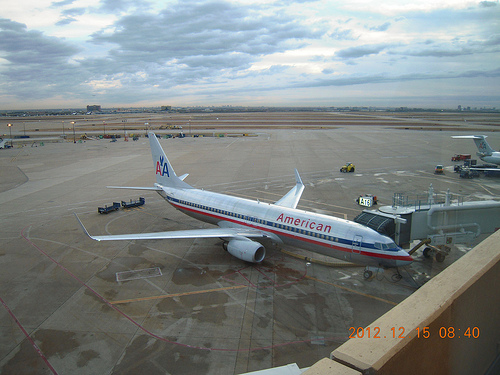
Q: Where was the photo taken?
A: It was taken at the airport.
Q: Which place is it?
A: It is an airport.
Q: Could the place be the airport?
A: Yes, it is the airport.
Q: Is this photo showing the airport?
A: Yes, it is showing the airport.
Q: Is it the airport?
A: Yes, it is the airport.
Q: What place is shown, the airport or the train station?
A: It is the airport.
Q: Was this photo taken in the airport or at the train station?
A: It was taken at the airport.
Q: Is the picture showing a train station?
A: No, the picture is showing an airport.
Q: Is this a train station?
A: No, it is an airport.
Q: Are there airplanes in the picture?
A: Yes, there is an airplane.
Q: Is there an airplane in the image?
A: Yes, there is an airplane.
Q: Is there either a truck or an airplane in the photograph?
A: Yes, there is an airplane.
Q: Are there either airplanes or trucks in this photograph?
A: Yes, there is an airplane.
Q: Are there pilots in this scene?
A: No, there are no pilots.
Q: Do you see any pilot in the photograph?
A: No, there are no pilots.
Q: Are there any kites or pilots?
A: No, there are no pilots or kites.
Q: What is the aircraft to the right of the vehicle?
A: The aircraft is an airplane.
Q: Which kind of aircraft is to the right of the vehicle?
A: The aircraft is an airplane.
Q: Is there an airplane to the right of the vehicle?
A: Yes, there is an airplane to the right of the vehicle.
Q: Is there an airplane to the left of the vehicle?
A: No, the airplane is to the right of the vehicle.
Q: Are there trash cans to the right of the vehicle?
A: No, there is an airplane to the right of the vehicle.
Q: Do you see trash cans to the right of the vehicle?
A: No, there is an airplane to the right of the vehicle.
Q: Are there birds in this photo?
A: No, there are no birds.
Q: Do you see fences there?
A: No, there are no fences.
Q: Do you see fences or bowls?
A: No, there are no fences or bowls.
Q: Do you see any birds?
A: No, there are no birds.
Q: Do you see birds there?
A: No, there are no birds.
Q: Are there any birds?
A: No, there are no birds.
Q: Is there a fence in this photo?
A: No, there are no fences.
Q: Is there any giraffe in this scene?
A: No, there are no giraffes.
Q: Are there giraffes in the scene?
A: No, there are no giraffes.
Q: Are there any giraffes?
A: No, there are no giraffes.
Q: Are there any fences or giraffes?
A: No, there are no giraffes or fences.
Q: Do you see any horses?
A: No, there are no horses.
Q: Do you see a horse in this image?
A: No, there are no horses.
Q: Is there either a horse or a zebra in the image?
A: No, there are no horses or zebras.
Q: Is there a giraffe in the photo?
A: No, there are no giraffes.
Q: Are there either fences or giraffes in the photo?
A: No, there are no giraffes or fences.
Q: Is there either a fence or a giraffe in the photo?
A: No, there are no giraffes or fences.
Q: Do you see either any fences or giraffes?
A: No, there are no giraffes or fences.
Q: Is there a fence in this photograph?
A: No, there are no fences.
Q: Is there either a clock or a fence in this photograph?
A: No, there are no fences or clocks.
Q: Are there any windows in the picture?
A: Yes, there are windows.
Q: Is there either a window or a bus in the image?
A: Yes, there are windows.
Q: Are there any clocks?
A: No, there are no clocks.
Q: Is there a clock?
A: No, there are no clocks.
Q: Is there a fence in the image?
A: No, there are no fences.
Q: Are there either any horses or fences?
A: No, there are no fences or horses.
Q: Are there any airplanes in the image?
A: Yes, there is an airplane.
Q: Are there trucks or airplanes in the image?
A: Yes, there is an airplane.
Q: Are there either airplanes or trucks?
A: Yes, there is an airplane.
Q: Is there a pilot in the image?
A: No, there are no pilots.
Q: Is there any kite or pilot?
A: No, there are no pilots or kites.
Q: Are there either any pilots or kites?
A: No, there are no pilots or kites.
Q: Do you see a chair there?
A: No, there are no chairs.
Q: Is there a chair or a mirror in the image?
A: No, there are no chairs or mirrors.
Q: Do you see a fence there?
A: No, there are no fences.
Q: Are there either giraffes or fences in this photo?
A: No, there are no fences or giraffes.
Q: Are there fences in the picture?
A: No, there are no fences.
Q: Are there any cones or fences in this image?
A: No, there are no fences or cones.